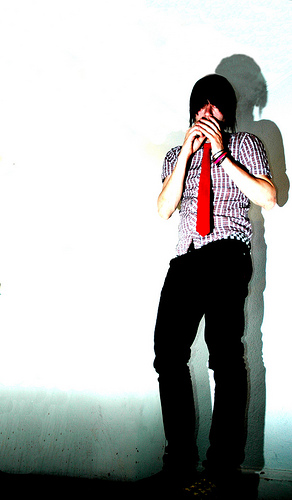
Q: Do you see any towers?
A: No, there are no towers.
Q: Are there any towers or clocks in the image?
A: No, there are no towers or clocks.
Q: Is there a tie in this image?
A: Yes, there is a tie.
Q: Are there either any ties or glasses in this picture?
A: Yes, there is a tie.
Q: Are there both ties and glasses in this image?
A: No, there is a tie but no glasses.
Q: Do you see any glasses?
A: No, there are no glasses.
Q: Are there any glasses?
A: No, there are no glasses.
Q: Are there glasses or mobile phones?
A: No, there are no glasses or mobile phones.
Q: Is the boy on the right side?
A: Yes, the boy is on the right of the image.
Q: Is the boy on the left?
A: No, the boy is on the right of the image.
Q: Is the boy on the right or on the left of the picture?
A: The boy is on the right of the image.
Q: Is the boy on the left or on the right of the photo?
A: The boy is on the right of the image.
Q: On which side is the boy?
A: The boy is on the right of the image.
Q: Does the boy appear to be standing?
A: Yes, the boy is standing.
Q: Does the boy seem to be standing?
A: Yes, the boy is standing.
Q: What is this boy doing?
A: The boy is standing.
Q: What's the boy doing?
A: The boy is standing.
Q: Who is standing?
A: The boy is standing.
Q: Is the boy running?
A: No, the boy is standing.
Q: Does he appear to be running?
A: No, the boy is standing.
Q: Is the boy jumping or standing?
A: The boy is standing.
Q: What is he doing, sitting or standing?
A: The boy is standing.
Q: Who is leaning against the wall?
A: The boy is leaning against the wall.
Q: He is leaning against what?
A: The boy is leaning against the wall.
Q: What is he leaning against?
A: The boy is leaning against the wall.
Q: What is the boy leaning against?
A: The boy is leaning against the wall.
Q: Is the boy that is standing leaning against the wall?
A: Yes, the boy is leaning against the wall.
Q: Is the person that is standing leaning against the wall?
A: Yes, the boy is leaning against the wall.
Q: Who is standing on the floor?
A: The boy is standing on the floor.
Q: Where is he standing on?
A: The boy is standing on the floor.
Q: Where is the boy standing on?
A: The boy is standing on the floor.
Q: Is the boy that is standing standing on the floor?
A: Yes, the boy is standing on the floor.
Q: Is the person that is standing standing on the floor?
A: Yes, the boy is standing on the floor.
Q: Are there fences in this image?
A: No, there are no fences.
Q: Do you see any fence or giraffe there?
A: No, there are no fences or giraffes.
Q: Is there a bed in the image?
A: No, there are no beds.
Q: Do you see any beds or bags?
A: No, there are no beds or bags.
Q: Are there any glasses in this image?
A: No, there are no glasses.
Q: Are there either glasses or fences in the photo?
A: No, there are no glasses or fences.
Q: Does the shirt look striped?
A: Yes, the shirt is striped.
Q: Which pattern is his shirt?
A: The shirt is striped.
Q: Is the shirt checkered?
A: No, the shirt is striped.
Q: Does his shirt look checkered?
A: No, the shirt is striped.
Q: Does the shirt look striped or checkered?
A: The shirt is striped.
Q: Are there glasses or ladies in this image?
A: No, there are no glasses or ladies.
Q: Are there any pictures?
A: No, there are no pictures.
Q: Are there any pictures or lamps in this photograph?
A: No, there are no pictures or lamps.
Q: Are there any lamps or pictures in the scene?
A: No, there are no pictures or lamps.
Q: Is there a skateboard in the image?
A: No, there are no skateboards.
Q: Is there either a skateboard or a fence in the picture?
A: No, there are no skateboards or fences.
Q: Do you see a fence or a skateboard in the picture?
A: No, there are no skateboards or fences.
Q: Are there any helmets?
A: No, there are no helmets.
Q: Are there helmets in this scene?
A: No, there are no helmets.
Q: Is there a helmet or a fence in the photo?
A: No, there are no helmets or fences.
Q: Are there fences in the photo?
A: No, there are no fences.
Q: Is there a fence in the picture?
A: No, there are no fences.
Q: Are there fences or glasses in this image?
A: No, there are no fences or glasses.